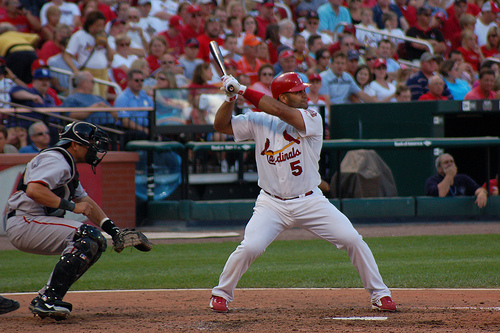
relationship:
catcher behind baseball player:
[0, 114, 153, 326] [190, 41, 403, 322]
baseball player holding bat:
[190, 41, 403, 322] [204, 31, 238, 104]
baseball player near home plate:
[190, 41, 403, 322] [309, 307, 403, 332]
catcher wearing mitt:
[0, 114, 153, 326] [106, 222, 155, 261]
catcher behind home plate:
[0, 114, 153, 326] [309, 307, 403, 332]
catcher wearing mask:
[0, 114, 153, 326] [81, 118, 121, 175]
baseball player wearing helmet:
[190, 41, 403, 322] [262, 70, 316, 104]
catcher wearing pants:
[0, 114, 153, 326] [0, 202, 95, 262]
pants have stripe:
[0, 202, 95, 262] [16, 215, 88, 236]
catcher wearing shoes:
[0, 114, 153, 326] [22, 284, 85, 324]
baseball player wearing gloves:
[190, 41, 403, 322] [215, 72, 252, 104]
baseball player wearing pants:
[190, 41, 403, 322] [210, 174, 398, 305]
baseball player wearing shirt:
[190, 41, 403, 322] [231, 105, 334, 201]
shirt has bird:
[231, 105, 334, 201] [259, 134, 275, 160]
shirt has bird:
[231, 105, 334, 201] [277, 126, 304, 153]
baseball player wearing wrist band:
[190, 41, 403, 322] [239, 81, 274, 109]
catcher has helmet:
[0, 114, 153, 326] [55, 119, 102, 145]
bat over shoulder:
[204, 31, 238, 104] [233, 106, 279, 146]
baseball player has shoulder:
[190, 41, 403, 322] [233, 106, 279, 146]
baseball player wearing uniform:
[190, 41, 403, 322] [207, 102, 400, 304]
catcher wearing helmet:
[0, 114, 153, 326] [55, 119, 102, 145]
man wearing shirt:
[113, 63, 161, 137] [116, 88, 158, 126]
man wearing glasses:
[113, 63, 161, 137] [128, 77, 147, 85]